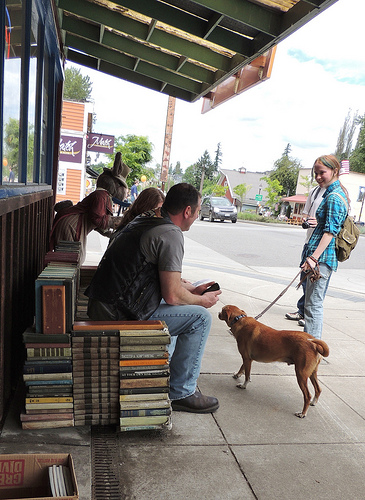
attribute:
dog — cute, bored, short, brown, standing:
[222, 299, 326, 413]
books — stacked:
[33, 240, 167, 452]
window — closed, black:
[0, 1, 63, 183]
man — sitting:
[88, 177, 220, 406]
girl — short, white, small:
[289, 149, 352, 350]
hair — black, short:
[167, 175, 197, 204]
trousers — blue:
[147, 303, 213, 399]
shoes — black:
[177, 385, 221, 417]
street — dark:
[184, 210, 355, 270]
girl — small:
[293, 135, 362, 332]